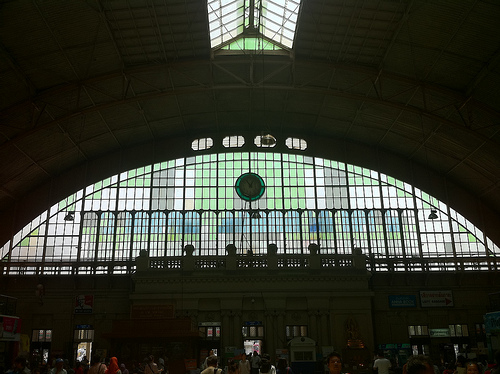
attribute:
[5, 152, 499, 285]
window — large, decorative, arched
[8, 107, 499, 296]
window — ticket, counter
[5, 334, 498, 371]
crowd — people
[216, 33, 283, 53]
window — green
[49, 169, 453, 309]
glass doorway — light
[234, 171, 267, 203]
clock — center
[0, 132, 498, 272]
glass — various, colored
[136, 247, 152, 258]
speaker — mounted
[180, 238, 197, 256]
speaker — mounted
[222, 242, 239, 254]
speaker — mounted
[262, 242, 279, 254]
speaker — mounted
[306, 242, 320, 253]
speaker — mounted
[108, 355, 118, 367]
head covering — red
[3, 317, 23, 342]
sign — store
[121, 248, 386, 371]
restaraunt — chicken , fast, food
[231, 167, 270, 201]
clock — large, circular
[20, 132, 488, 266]
wall — glass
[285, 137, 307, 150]
window — small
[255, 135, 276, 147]
window — small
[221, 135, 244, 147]
window — small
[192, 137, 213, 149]
window — small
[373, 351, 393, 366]
shirt — white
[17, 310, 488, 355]
counters — ticket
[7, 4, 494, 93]
roof — rounded